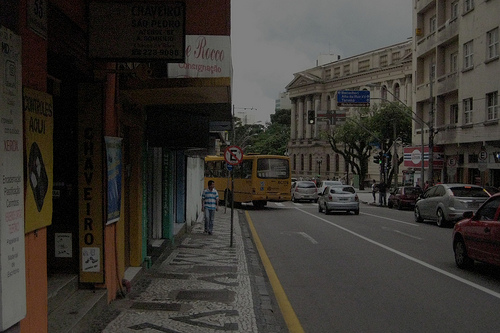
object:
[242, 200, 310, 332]
line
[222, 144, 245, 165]
sign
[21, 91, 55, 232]
advertisement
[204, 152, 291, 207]
bus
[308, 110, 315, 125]
light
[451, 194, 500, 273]
car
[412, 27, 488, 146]
buidling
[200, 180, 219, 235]
man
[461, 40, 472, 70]
window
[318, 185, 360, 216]
car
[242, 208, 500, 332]
road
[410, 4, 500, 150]
building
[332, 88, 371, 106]
sign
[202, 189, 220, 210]
shirt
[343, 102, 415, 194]
trees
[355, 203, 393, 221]
sidewalk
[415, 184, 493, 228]
cars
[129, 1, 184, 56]
lettering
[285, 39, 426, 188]
buildings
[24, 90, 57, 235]
sign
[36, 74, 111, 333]
doorway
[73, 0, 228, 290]
building